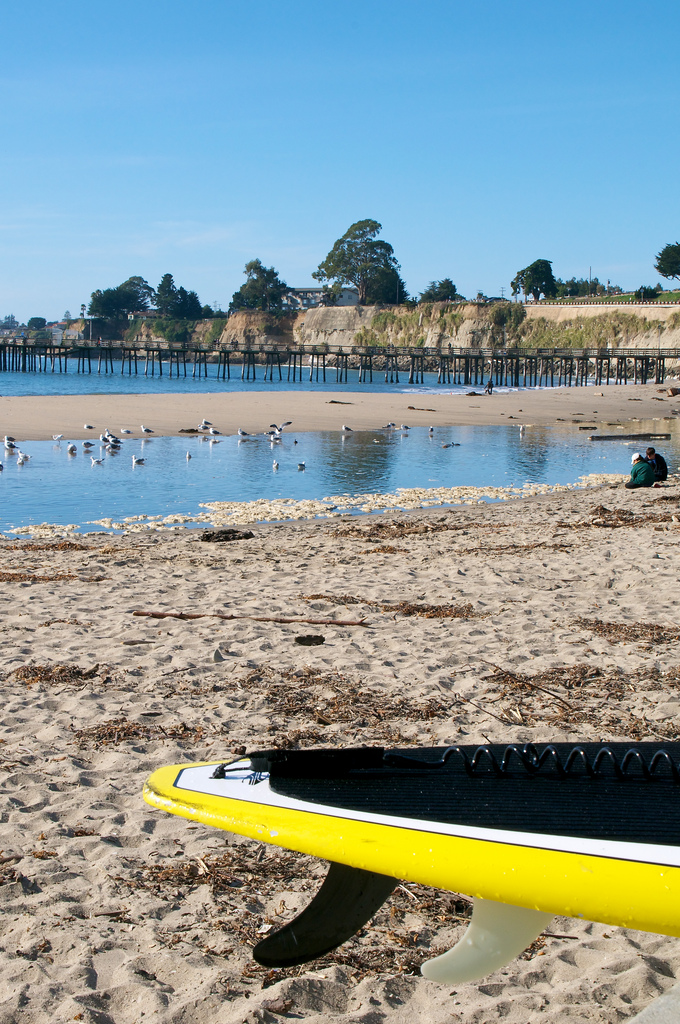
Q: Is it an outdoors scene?
A: Yes, it is outdoors.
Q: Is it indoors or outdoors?
A: It is outdoors.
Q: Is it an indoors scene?
A: No, it is outdoors.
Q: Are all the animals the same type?
A: Yes, all the animals are birds.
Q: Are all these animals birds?
A: Yes, all the animals are birds.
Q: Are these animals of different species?
A: No, all the animals are birds.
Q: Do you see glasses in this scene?
A: No, there are no glasses.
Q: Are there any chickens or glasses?
A: No, there are no glasses or chickens.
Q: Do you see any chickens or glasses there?
A: No, there are no glasses or chickens.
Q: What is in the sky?
A: The clouds are in the sky.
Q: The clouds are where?
A: The clouds are in the sky.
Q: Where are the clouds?
A: The clouds are in the sky.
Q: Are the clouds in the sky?
A: Yes, the clouds are in the sky.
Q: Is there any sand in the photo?
A: Yes, there is sand.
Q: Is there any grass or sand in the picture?
A: Yes, there is sand.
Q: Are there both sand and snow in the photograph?
A: No, there is sand but no snow.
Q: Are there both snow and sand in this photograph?
A: No, there is sand but no snow.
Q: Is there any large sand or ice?
A: Yes, there is large sand.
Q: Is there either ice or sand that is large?
A: Yes, the sand is large.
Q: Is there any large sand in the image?
A: Yes, there is large sand.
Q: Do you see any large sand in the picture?
A: Yes, there is large sand.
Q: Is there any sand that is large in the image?
A: Yes, there is large sand.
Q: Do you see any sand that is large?
A: Yes, there is large sand.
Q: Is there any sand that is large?
A: Yes, there is sand that is large.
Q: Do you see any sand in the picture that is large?
A: Yes, there is sand that is large.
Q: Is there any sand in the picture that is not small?
A: Yes, there is large sand.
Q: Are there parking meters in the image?
A: No, there are no parking meters.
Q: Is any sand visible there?
A: Yes, there is sand.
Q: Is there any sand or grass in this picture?
A: Yes, there is sand.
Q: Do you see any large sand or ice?
A: Yes, there is large sand.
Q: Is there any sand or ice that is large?
A: Yes, the sand is large.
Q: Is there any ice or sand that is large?
A: Yes, the sand is large.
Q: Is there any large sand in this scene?
A: Yes, there is large sand.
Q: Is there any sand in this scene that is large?
A: Yes, there is sand that is large.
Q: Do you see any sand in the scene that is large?
A: Yes, there is sand that is large.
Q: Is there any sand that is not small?
A: Yes, there is large sand.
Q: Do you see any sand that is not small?
A: Yes, there is large sand.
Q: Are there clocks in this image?
A: No, there are no clocks.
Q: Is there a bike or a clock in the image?
A: No, there are no clocks or bikes.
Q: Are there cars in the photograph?
A: No, there are no cars.